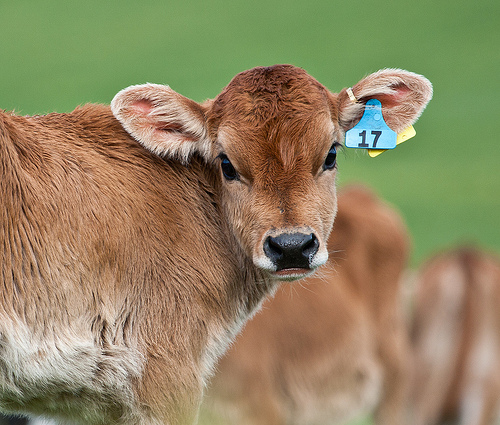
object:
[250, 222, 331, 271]
nose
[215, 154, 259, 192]
beady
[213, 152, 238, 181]
eyes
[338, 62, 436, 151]
ear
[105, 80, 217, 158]
ear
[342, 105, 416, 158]
tag